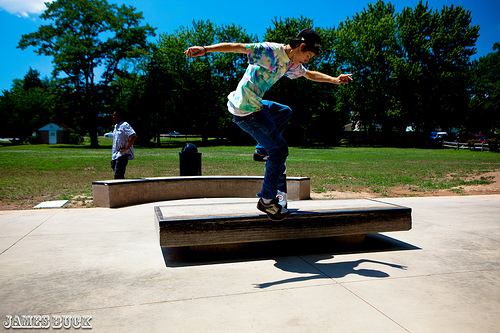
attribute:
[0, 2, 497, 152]
trees — tall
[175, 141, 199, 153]
top — black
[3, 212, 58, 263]
cracks — Large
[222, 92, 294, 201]
pants — long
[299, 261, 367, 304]
cracks — Large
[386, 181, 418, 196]
patche — dirt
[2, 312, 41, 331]
james — white, grey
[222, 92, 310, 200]
pants — blue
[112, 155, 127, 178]
pants — long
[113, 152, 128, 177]
pants — blue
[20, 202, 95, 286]
cracks — Large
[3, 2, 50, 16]
cloud — single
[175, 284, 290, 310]
cracks — Large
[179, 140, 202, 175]
trash can — black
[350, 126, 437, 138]
flowers — yellow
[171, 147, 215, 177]
can — public, trash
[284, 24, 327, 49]
hat — backwards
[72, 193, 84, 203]
flowers — yellow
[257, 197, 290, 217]
shoes — black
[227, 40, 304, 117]
shirt —  tye dye, colorful